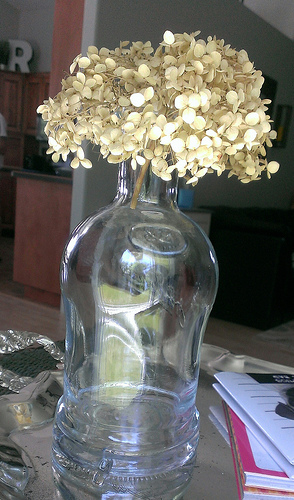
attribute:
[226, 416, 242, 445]
book cover — pink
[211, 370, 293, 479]
notebook — white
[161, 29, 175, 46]
petal — light colored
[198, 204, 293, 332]
couch — black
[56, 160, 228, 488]
vase — glass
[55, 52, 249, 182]
flower — light colored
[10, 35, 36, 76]
letter — R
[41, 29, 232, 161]
bouquet — white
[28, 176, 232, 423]
vase — clear, glass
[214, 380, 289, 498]
book — pink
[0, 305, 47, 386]
ribbon — silver